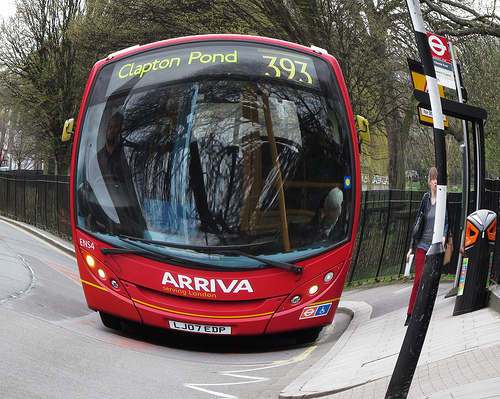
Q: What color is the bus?
A: Red.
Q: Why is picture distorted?
A: Mirror shot.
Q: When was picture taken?
A: Daytime.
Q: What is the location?
A: Bus stop.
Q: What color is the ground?
A: Grey.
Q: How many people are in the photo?
A: One.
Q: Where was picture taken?
A: On the street.